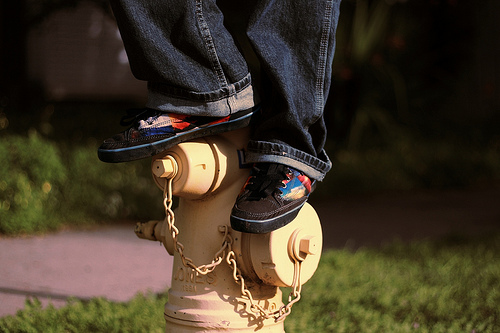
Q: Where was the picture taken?
A: It was taken at the sidewalk.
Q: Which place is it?
A: It is a sidewalk.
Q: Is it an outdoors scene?
A: Yes, it is outdoors.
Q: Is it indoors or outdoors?
A: It is outdoors.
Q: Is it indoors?
A: No, it is outdoors.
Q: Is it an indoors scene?
A: No, it is outdoors.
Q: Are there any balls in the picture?
A: No, there are no balls.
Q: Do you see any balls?
A: No, there are no balls.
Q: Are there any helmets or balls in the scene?
A: No, there are no balls or helmets.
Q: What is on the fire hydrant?
A: The shoe is on the fire hydrant.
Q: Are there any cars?
A: No, there are no cars.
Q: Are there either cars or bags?
A: No, there are no cars or bags.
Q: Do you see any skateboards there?
A: No, there are no skateboards.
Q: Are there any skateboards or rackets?
A: No, there are no skateboards or rackets.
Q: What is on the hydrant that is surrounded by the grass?
A: The shoe is on the hydrant.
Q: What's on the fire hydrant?
A: The shoe is on the hydrant.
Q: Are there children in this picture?
A: Yes, there is a child.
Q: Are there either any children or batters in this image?
A: Yes, there is a child.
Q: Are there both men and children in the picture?
A: No, there is a child but no men.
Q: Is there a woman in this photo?
A: No, there are no women.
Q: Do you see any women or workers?
A: No, there are no women or workers.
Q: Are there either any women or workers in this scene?
A: No, there are no women or workers.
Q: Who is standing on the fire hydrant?
A: The child is standing on the fire hydrant.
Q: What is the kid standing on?
A: The kid is standing on the fire hydrant.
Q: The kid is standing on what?
A: The kid is standing on the fire hydrant.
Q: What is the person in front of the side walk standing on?
A: The kid is standing on the fire hydrant.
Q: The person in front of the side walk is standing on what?
A: The kid is standing on the fire hydrant.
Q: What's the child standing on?
A: The kid is standing on the fire hydrant.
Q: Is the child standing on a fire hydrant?
A: Yes, the child is standing on a fire hydrant.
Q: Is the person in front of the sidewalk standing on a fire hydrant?
A: Yes, the child is standing on a fire hydrant.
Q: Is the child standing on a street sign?
A: No, the child is standing on a fire hydrant.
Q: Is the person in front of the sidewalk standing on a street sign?
A: No, the child is standing on a fire hydrant.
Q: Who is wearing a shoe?
A: The child is wearing a shoe.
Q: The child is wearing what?
A: The child is wearing a shoe.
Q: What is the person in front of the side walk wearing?
A: The child is wearing a shoe.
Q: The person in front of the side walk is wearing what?
A: The child is wearing a shoe.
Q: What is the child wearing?
A: The child is wearing a shoe.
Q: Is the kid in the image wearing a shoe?
A: Yes, the kid is wearing a shoe.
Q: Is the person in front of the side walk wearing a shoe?
A: Yes, the kid is wearing a shoe.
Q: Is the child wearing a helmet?
A: No, the child is wearing a shoe.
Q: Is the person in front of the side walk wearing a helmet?
A: No, the child is wearing a shoe.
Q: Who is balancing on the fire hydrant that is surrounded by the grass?
A: The child is balancing on the hydrant.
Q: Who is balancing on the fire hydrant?
A: The child is balancing on the hydrant.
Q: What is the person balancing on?
A: The kid is balancing on the fire hydrant.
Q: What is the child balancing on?
A: The kid is balancing on the fire hydrant.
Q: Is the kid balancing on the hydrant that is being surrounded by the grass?
A: Yes, the kid is balancing on the hydrant.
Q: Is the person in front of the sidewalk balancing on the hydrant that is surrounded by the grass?
A: Yes, the kid is balancing on the hydrant.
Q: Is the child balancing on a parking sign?
A: No, the child is balancing on the hydrant.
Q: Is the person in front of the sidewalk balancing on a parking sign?
A: No, the child is balancing on the hydrant.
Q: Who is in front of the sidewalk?
A: The child is in front of the side walk.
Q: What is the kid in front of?
A: The kid is in front of the sidewalk.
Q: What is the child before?
A: The kid is in front of the sidewalk.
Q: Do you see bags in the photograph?
A: No, there are no bags.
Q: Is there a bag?
A: No, there are no bags.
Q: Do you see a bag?
A: No, there are no bags.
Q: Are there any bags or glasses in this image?
A: No, there are no bags or glasses.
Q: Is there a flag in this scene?
A: No, there are no flags.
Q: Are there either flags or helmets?
A: No, there are no flags or helmets.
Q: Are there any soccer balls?
A: No, there are no soccer balls.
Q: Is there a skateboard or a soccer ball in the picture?
A: No, there are no soccer balls or skateboards.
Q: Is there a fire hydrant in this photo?
A: Yes, there is a fire hydrant.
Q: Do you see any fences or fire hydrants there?
A: Yes, there is a fire hydrant.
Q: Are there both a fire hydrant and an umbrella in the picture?
A: No, there is a fire hydrant but no umbrellas.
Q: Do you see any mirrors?
A: No, there are no mirrors.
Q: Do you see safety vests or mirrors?
A: No, there are no mirrors or safety vests.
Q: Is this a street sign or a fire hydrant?
A: This is a fire hydrant.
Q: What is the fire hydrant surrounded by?
A: The fire hydrant is surrounded by the grass.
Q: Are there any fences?
A: No, there are no fences.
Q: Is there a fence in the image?
A: No, there are no fences.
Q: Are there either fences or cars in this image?
A: No, there are no fences or cars.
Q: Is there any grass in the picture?
A: Yes, there is grass.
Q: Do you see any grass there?
A: Yes, there is grass.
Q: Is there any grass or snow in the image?
A: Yes, there is grass.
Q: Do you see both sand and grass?
A: No, there is grass but no sand.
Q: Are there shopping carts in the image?
A: No, there are no shopping carts.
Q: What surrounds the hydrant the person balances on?
A: The grass surrounds the fire hydrant.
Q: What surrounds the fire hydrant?
A: The grass surrounds the fire hydrant.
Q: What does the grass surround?
A: The grass surrounds the hydrant.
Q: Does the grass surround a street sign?
A: No, the grass surrounds a fire hydrant.